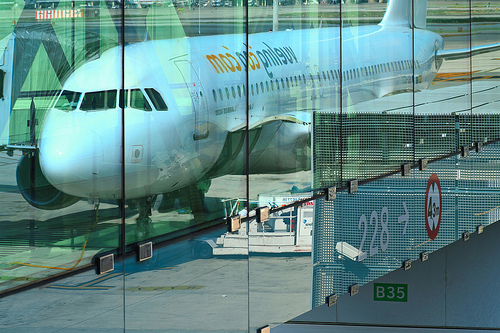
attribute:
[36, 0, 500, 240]
airplane — parked, big, white, large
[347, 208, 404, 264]
228 — white, pointing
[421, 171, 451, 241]
sign — red, white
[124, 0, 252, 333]
windows — large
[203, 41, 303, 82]
logo — on left side, yellow, gray, orange, grey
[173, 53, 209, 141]
door — for loading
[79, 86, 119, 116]
windshield — large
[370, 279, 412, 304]
b35 — white, written